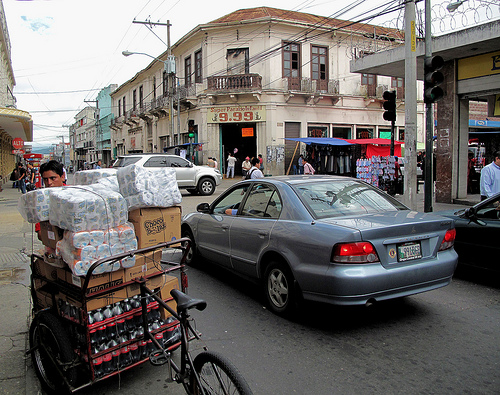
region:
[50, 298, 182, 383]
sodas on a bike basket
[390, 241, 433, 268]
license plate of gray car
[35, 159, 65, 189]
boy standing behind bicycle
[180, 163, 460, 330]
gray car driving down street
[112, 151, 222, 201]
silver suv driving down street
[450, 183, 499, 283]
black car parked on street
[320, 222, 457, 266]
red tail lights of gray car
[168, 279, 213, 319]
black bicycle seat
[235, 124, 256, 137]
orange sign on door of building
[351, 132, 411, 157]
red roof across street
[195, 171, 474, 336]
the car is blue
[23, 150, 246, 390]
man pushing a cart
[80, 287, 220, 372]
bottles are on cart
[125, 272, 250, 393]
bicycle behind the cart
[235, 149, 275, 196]
person crossing the street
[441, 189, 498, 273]
the car is black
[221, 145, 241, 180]
person standing in front of building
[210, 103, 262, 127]
red numbers on building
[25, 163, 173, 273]
white packaging on cart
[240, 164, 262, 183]
man wearing a backpack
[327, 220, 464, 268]
Brake lights engaged on car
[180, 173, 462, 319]
Car has come to a stop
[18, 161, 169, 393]
Man pushing supplies on the street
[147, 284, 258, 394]
Part of a black bicycle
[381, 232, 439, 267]
License plate on a light blue car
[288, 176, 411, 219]
Reflection off the back window of the car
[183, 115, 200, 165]
Green traffic light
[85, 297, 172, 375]
Cases of Coca Cola soda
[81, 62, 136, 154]
Green building front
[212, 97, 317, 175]
Men gathered in front of the store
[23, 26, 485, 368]
a busy city street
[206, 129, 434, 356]
this car is grey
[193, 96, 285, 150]
the sign says 9.99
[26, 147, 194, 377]
a man delivering goods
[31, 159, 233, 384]
the man has a delivery bike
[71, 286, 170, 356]
bottles of coca cola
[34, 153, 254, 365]
the bike is black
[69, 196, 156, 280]
the man has paper towels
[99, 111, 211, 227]
a white suv on the street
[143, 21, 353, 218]
the building has two stories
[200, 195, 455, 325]
gray car stopped in road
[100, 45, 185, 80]
street light on wooden pole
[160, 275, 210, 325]
black bicycle seat on bike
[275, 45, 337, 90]
broken old building windows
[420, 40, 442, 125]
black traffic light on pole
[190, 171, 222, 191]
black rubber car tire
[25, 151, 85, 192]
mans with black hair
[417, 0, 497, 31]
grey metal barbwire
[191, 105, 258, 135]
store sign with red letters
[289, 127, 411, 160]
blue and red tent